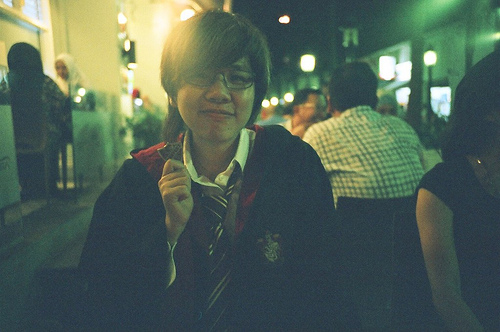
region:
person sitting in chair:
[61, 9, 363, 330]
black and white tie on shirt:
[205, 191, 228, 313]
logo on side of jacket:
[260, 225, 286, 263]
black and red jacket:
[71, 125, 316, 310]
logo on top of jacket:
[157, 142, 184, 174]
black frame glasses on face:
[178, 63, 263, 92]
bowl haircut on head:
[169, 19, 266, 79]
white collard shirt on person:
[172, 137, 254, 192]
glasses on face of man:
[288, 97, 328, 114]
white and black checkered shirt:
[334, 108, 409, 188]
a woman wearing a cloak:
[75, 13, 362, 329]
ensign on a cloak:
[255, 222, 287, 274]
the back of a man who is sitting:
[308, 64, 428, 199]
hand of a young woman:
[157, 157, 201, 241]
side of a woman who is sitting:
[407, 53, 499, 330]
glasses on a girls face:
[181, 66, 254, 88]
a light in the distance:
[377, 53, 396, 83]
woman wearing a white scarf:
[49, 55, 83, 96]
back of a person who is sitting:
[0, 45, 73, 160]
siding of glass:
[69, 110, 119, 184]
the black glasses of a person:
[186, 65, 256, 90]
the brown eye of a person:
[194, 70, 208, 82]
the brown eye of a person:
[229, 72, 244, 84]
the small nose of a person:
[206, 90, 233, 102]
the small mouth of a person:
[202, 106, 234, 121]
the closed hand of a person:
[159, 158, 193, 221]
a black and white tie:
[188, 160, 235, 324]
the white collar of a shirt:
[177, 125, 261, 182]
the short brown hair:
[155, 13, 265, 133]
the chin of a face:
[197, 120, 237, 140]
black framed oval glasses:
[188, 74, 282, 104]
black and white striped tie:
[185, 171, 239, 311]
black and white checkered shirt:
[310, 108, 404, 225]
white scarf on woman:
[46, 43, 87, 99]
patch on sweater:
[265, 212, 305, 277]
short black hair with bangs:
[115, 23, 290, 49]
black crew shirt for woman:
[418, 154, 494, 239]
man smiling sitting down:
[294, 86, 339, 138]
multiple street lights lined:
[283, 31, 453, 99]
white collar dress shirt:
[168, 146, 325, 231]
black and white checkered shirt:
[291, 98, 436, 204]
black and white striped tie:
[177, 161, 249, 326]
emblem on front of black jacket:
[248, 220, 294, 279]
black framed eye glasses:
[180, 56, 261, 97]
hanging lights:
[267, 8, 322, 75]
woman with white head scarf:
[47, 48, 90, 100]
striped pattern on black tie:
[210, 260, 233, 317]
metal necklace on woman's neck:
[470, 151, 498, 181]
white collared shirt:
[176, 128, 246, 263]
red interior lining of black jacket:
[127, 143, 267, 309]